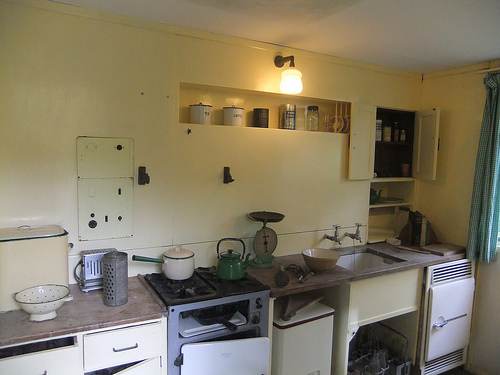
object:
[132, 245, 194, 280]
pot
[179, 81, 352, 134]
built-in shelf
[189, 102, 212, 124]
containers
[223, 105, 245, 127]
containers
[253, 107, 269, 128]
containers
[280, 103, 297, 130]
containers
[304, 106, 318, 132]
containers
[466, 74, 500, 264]
curtain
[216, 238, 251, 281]
tea kettle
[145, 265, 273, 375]
stove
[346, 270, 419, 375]
dishwasher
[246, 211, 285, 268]
scale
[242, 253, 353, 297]
counter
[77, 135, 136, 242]
sockets